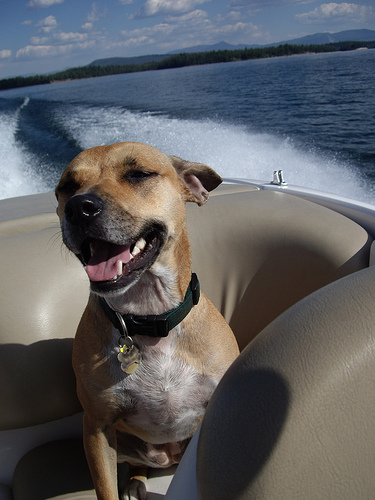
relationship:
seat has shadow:
[1, 172, 374, 497] [1, 333, 296, 498]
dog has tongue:
[42, 139, 226, 499] [83, 237, 136, 288]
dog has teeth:
[42, 139, 226, 499] [84, 235, 147, 278]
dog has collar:
[42, 139, 226, 499] [92, 267, 204, 377]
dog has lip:
[42, 139, 226, 499] [73, 219, 170, 299]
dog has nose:
[42, 139, 226, 499] [60, 192, 107, 230]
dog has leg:
[42, 139, 226, 499] [73, 414, 132, 499]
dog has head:
[42, 139, 226, 499] [49, 138, 228, 315]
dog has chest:
[42, 139, 226, 499] [97, 329, 221, 447]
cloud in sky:
[17, 15, 61, 37] [1, 0, 374, 79]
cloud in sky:
[76, 17, 97, 36] [1, 0, 374, 79]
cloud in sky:
[108, 33, 158, 53] [1, 0, 374, 79]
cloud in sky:
[160, 7, 211, 28] [1, 0, 374, 79]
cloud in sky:
[284, 1, 374, 34] [1, 0, 374, 79]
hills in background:
[165, 26, 373, 58] [1, 21, 374, 98]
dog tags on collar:
[110, 311, 146, 381] [92, 267, 204, 377]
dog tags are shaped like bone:
[110, 311, 146, 381] [115, 344, 144, 378]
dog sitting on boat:
[42, 139, 226, 499] [5, 161, 375, 499]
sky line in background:
[1, 24, 374, 96] [1, 21, 374, 98]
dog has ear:
[42, 139, 226, 499] [164, 148, 228, 213]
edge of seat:
[161, 265, 370, 500] [1, 172, 374, 497]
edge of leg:
[79, 428, 100, 499] [73, 414, 132, 499]